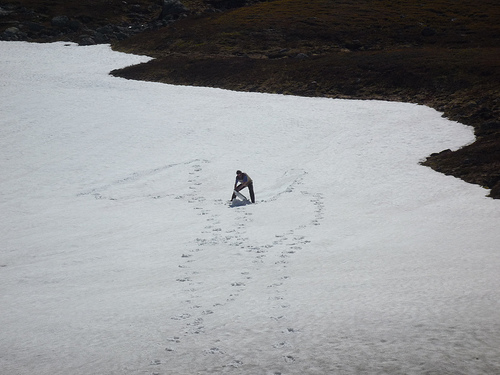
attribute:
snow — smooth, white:
[66, 109, 123, 131]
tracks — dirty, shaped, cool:
[294, 187, 323, 277]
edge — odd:
[281, 84, 386, 118]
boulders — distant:
[61, 17, 114, 45]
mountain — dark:
[458, 120, 494, 167]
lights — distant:
[122, 14, 183, 37]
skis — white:
[227, 186, 262, 219]